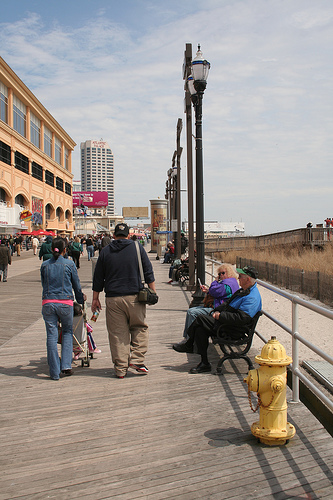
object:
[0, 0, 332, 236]
sky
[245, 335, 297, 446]
fire hydrant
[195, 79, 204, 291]
pole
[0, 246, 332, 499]
boardwalk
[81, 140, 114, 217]
building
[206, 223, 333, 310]
beach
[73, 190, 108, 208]
banner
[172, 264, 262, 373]
man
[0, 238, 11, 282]
people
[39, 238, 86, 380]
woman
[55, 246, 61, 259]
ponytail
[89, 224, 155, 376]
man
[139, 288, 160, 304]
camera bag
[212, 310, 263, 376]
bench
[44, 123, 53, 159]
window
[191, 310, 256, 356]
pants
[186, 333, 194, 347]
socks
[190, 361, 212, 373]
shoes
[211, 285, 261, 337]
coat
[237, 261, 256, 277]
hat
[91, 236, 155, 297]
shirt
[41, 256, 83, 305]
jacket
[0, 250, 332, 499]
floor